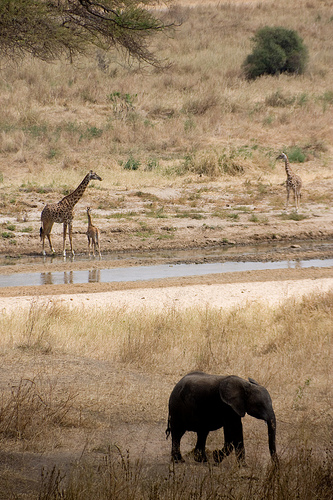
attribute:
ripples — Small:
[37, 266, 214, 283]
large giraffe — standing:
[27, 167, 104, 256]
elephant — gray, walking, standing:
[154, 362, 288, 472]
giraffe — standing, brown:
[267, 149, 312, 220]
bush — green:
[230, 19, 316, 85]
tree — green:
[7, 4, 170, 69]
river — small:
[7, 247, 329, 283]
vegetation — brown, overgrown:
[14, 89, 328, 147]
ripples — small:
[67, 267, 92, 275]